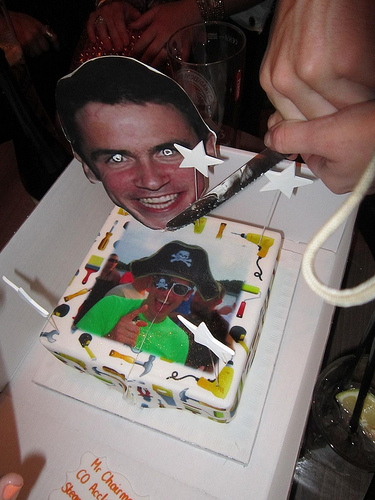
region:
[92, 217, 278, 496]
cake on white board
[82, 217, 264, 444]
white cake with tools on it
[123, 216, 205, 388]
man in green shirt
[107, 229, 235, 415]
smiling man on cake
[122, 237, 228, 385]
man in pirate hat on cake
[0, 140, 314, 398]
four white stars on cake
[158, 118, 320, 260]
someone holding knife to cut cake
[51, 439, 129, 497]
orange writing by cake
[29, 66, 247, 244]
cardboard cut out of mans head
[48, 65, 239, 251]
smiling mans head on cardboard cutout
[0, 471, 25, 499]
someones finger with orange nail polish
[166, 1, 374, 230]
two hands holding a knife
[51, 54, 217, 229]
a cut out of someones smiling face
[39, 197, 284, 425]
a custom cake with that smiling face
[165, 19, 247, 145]
a beer glass from a restaurant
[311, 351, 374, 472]
an overhead view of a glass with a drink in it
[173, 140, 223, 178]
a white star cake decoration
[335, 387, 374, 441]
a lime wedge in cocktail drink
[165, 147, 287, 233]
a silver steak knife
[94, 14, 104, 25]
a ring on a young girls finger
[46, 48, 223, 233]
Picture of man nex a cake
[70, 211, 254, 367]
Picture of man on cake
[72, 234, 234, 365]
Man wearing pirate hat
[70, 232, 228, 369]
Man wears green shirt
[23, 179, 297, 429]
Cake decorated with male figures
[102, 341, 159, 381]
Hammer with yellow handle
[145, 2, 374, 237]
Person holding a knife with both hands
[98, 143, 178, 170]
Eyes of person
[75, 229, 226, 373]
Person points with finger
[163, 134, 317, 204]
Stars on cake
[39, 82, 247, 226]
cutout of mans head in photo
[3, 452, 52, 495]
can see painted finger nail in photo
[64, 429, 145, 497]
white paper that says mr chairman in photo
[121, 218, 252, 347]
man wearing pirate hat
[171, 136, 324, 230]
two stars close together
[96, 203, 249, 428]
cake with tools on it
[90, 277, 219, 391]
man in green shirt on photo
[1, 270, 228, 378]
two stars spread apart in photo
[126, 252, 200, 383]
man smiling on cake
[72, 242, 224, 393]
man pointing finger on cake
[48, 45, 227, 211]
A scary looking face.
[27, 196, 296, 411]
A weird looking cake with a picture on it.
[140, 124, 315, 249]
A sharp knife covered in frosting.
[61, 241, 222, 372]
The image of a a pirate painted on a cake.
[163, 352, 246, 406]
The mage of a drill.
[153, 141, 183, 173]
demonic looking left eye.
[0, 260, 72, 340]
A plastic star sticking out of a cake.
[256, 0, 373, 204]
human hands holding a knife.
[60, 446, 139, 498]
writing on the side of a box.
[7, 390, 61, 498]
part of a human hand.